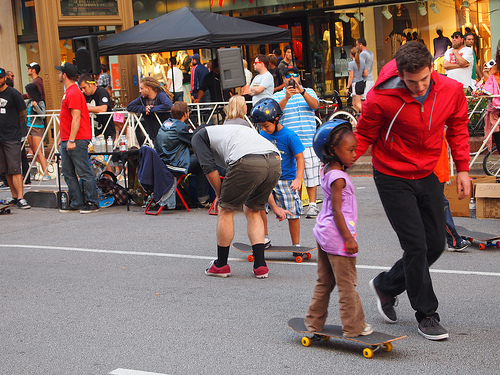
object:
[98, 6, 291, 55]
canopy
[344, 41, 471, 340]
man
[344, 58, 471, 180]
jacket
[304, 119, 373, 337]
girl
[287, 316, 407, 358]
skateboard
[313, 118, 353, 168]
helmet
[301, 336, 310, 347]
wheels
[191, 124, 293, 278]
man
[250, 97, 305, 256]
boy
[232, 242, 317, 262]
skateboard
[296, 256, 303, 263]
wheels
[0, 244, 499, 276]
line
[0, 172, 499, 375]
street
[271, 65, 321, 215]
man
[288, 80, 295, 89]
cellphone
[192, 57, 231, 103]
person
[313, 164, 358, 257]
shirt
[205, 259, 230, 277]
shoes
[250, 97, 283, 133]
helmet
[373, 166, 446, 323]
pants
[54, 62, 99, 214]
man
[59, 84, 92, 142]
shirt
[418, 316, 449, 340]
shoes